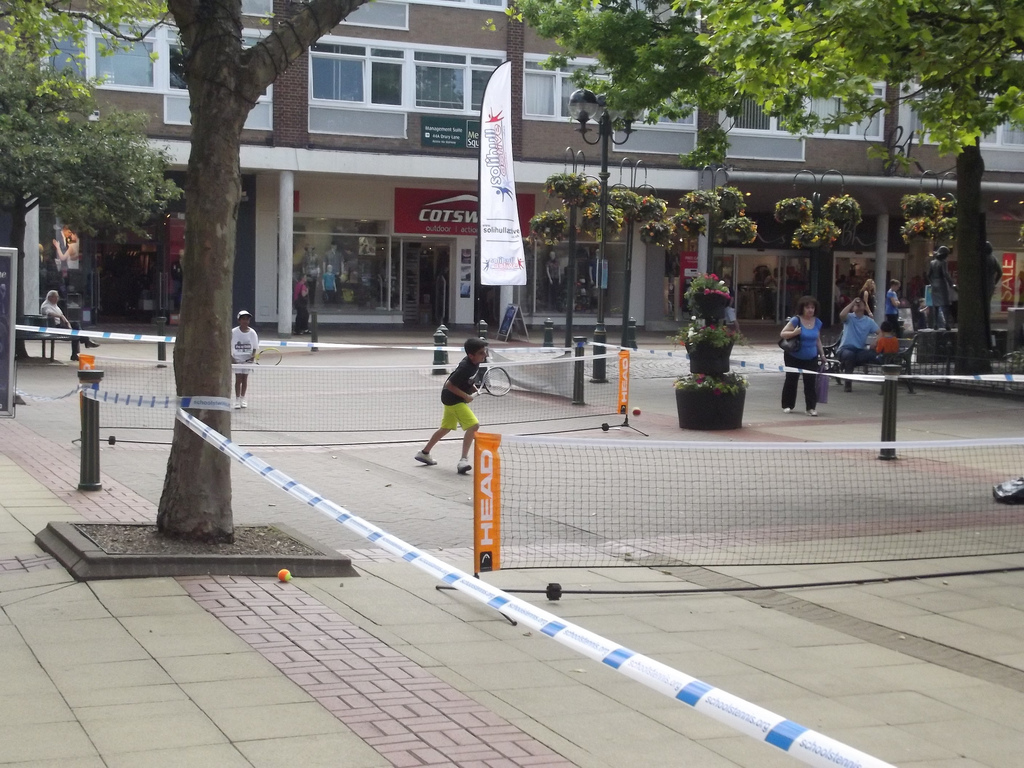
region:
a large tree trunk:
[122, 2, 363, 575]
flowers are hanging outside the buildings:
[780, 181, 863, 239]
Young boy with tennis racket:
[420, 264, 537, 492]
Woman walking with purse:
[780, 280, 835, 427]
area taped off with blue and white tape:
[46, 313, 925, 766]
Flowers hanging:
[517, 166, 1023, 284]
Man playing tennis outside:
[218, 304, 332, 413]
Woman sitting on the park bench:
[25, 251, 89, 375]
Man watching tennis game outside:
[838, 263, 936, 378]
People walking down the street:
[859, 276, 970, 334]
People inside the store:
[297, 223, 396, 309]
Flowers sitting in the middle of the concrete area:
[673, 248, 756, 442]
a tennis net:
[482, 435, 1021, 562]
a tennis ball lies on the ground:
[270, 564, 289, 585]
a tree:
[166, 0, 359, 538]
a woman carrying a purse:
[782, 292, 828, 414]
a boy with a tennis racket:
[431, 334, 488, 472]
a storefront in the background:
[283, 172, 635, 340]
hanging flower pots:
[782, 196, 865, 247]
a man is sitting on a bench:
[842, 292, 882, 390]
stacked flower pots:
[684, 283, 743, 432]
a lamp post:
[575, 89, 630, 390]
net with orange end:
[470, 430, 1021, 580]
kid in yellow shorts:
[416, 334, 509, 486]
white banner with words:
[477, 58, 526, 289]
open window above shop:
[307, 35, 410, 105]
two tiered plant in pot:
[676, 266, 744, 429]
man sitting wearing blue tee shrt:
[838, 291, 878, 391]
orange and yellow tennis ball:
[275, 566, 292, 582]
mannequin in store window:
[318, 258, 341, 307]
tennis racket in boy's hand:
[465, 364, 510, 400]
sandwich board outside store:
[498, 302, 527, 341]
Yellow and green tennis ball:
[264, 557, 318, 589]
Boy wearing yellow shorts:
[420, 318, 497, 478]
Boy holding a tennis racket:
[414, 301, 525, 483]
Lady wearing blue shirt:
[770, 267, 834, 419]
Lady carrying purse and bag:
[762, 272, 840, 429]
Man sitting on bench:
[34, 257, 105, 368]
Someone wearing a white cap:
[221, 282, 279, 429]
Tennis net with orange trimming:
[438, 421, 1023, 595]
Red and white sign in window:
[982, 198, 1022, 339]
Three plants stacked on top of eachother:
[676, 253, 757, 449]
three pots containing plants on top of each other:
[679, 269, 749, 429]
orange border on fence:
[474, 434, 532, 572]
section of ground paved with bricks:
[302, 627, 455, 742]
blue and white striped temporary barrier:
[582, 614, 846, 764]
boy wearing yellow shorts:
[438, 394, 492, 430]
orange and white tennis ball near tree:
[189, 459, 304, 584]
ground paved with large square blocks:
[13, 587, 197, 731]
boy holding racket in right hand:
[446, 340, 514, 405]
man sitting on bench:
[824, 291, 932, 375]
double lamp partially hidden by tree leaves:
[568, 75, 639, 377]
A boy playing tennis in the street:
[399, 317, 513, 479]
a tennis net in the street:
[467, 429, 1022, 588]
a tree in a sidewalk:
[44, 9, 307, 567]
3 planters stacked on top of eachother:
[673, 269, 747, 432]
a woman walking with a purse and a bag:
[771, 291, 828, 418]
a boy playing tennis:
[228, 306, 260, 415]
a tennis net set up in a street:
[70, 350, 639, 439]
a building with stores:
[0, 1, 1015, 344]